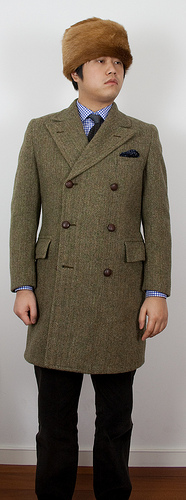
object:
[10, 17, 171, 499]
man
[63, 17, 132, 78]
cap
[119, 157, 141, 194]
pocket square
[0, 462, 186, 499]
floor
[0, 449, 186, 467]
baseboard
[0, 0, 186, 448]
wall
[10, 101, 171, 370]
peacoat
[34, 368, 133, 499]
pants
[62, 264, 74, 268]
hole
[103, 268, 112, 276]
button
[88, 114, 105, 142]
tie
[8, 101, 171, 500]
outfit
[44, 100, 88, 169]
lapel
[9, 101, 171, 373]
cold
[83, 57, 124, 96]
face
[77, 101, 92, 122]
collar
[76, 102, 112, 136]
shirt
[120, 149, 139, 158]
handkerchief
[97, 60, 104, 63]
eye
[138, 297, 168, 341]
hand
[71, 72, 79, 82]
ear